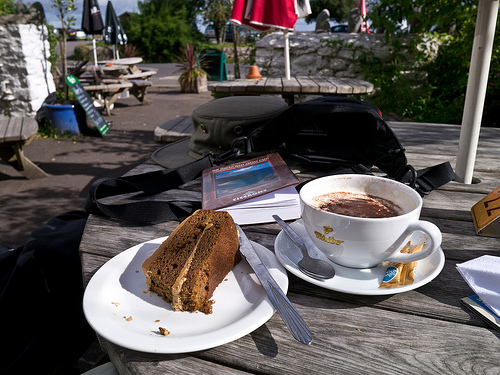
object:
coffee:
[297, 172, 443, 270]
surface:
[316, 304, 500, 375]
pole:
[439, 0, 500, 187]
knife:
[230, 221, 317, 347]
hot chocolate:
[331, 189, 386, 212]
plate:
[77, 206, 291, 356]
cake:
[139, 207, 242, 318]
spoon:
[265, 206, 341, 284]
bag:
[82, 104, 458, 239]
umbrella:
[222, 0, 317, 35]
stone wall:
[251, 27, 495, 108]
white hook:
[198, 146, 305, 228]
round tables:
[75, 115, 499, 375]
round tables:
[202, 66, 377, 98]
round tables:
[65, 55, 159, 83]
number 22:
[482, 187, 499, 218]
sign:
[464, 180, 499, 233]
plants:
[167, 36, 210, 96]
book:
[200, 150, 304, 225]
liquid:
[304, 173, 410, 224]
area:
[0, 112, 39, 139]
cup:
[302, 174, 407, 215]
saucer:
[308, 265, 436, 299]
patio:
[145, 51, 385, 144]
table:
[77, 107, 500, 375]